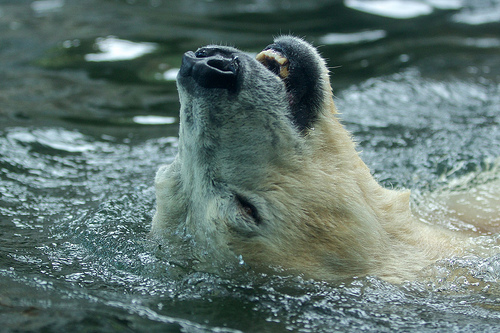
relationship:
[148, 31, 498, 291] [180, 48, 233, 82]
bear has nostril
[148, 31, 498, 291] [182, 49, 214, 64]
bear has nostril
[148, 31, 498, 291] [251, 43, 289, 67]
bear has teeth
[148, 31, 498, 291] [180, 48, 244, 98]
bear has nose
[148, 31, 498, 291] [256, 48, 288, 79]
bear has teeth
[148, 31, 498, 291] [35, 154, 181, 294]
bear submerged in water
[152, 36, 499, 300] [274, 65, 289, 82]
polar bear has tooth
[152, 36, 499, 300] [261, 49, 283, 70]
polar bear has tooth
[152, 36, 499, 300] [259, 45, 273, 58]
polar bear has tooth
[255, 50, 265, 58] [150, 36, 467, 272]
tooth of bear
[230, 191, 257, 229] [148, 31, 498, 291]
eye of bear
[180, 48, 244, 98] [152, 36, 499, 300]
nose of polar bear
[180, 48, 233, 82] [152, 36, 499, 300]
nostril of polar bear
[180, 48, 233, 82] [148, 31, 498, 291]
nostril of bear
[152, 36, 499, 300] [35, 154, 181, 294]
polar bear in water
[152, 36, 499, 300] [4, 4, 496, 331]
polar bear in water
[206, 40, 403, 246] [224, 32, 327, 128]
bear with mouth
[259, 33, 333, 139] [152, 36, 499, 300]
bottom jaw of polar bear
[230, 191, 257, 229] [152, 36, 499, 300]
eye of polar bear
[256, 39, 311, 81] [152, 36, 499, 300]
teeth of polar bear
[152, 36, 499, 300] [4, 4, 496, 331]
polar bear floating in water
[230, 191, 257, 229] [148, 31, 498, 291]
eye closed on bear